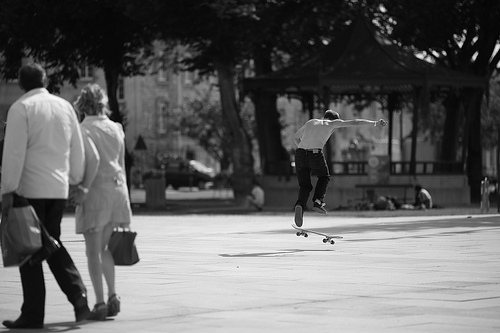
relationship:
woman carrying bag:
[74, 81, 141, 317] [106, 225, 142, 267]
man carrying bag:
[3, 62, 90, 330] [1, 202, 43, 267]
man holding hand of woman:
[3, 62, 94, 330] [74, 81, 141, 317]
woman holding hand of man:
[74, 81, 141, 317] [3, 62, 94, 330]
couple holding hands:
[4, 62, 132, 325] [64, 177, 91, 209]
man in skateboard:
[288, 107, 383, 239] [288, 218, 353, 250]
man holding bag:
[3, 62, 90, 330] [109, 225, 141, 265]